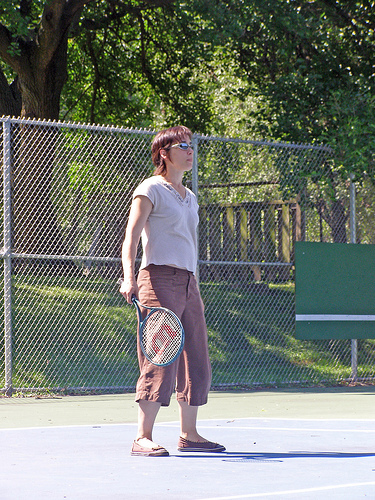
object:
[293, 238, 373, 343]
green board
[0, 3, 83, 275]
tree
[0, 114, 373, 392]
fence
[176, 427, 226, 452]
foot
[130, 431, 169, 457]
foot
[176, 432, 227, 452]
sneaker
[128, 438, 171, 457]
sneaker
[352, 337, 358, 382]
pole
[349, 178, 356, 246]
pole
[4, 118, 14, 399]
pole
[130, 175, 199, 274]
shirt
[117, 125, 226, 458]
girl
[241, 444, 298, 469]
shade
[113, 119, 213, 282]
flag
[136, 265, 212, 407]
short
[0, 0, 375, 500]
tennis court.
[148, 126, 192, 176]
hair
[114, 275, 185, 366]
racket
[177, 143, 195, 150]
sunglasses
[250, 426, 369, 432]
lines